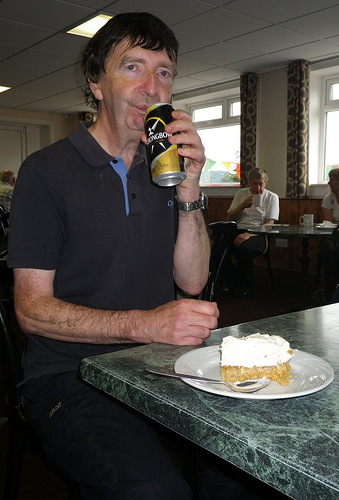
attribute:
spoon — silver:
[147, 363, 271, 395]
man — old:
[221, 161, 283, 231]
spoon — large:
[143, 362, 273, 398]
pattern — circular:
[284, 108, 308, 141]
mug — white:
[296, 208, 314, 227]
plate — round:
[167, 336, 337, 405]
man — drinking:
[5, 12, 225, 359]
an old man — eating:
[0, 8, 240, 347]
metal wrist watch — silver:
[166, 188, 219, 214]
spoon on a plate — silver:
[135, 357, 271, 395]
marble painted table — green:
[73, 303, 337, 499]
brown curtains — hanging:
[231, 64, 317, 199]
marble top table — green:
[290, 311, 337, 353]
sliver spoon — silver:
[144, 363, 274, 397]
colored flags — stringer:
[197, 150, 248, 184]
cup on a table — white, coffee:
[291, 211, 319, 228]